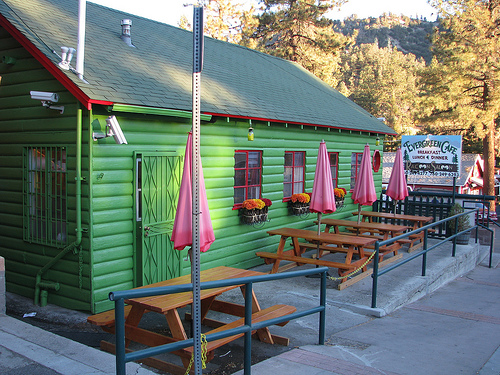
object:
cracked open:
[136, 150, 144, 280]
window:
[232, 147, 268, 207]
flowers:
[243, 199, 261, 207]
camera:
[104, 119, 129, 145]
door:
[135, 151, 187, 289]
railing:
[110, 266, 333, 371]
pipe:
[30, 100, 99, 316]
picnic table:
[271, 225, 379, 287]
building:
[0, 0, 399, 316]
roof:
[0, 0, 402, 138]